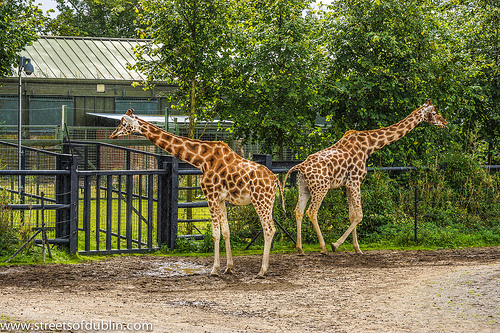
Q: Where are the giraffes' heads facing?
A: Opposite each other.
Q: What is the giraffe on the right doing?
A: Walking.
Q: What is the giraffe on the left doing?
A: Standing.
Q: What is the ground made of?
A: Dirt.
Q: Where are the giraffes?
A: Zoo.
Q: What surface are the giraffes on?
A: Dirt.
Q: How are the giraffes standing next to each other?
A: Back-to-back.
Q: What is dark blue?
A: The gate.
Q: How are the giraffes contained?
A: Fence.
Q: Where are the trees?
A: Behind the fence.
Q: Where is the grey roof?
A: On the building.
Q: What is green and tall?
A: The trees.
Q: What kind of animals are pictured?
A: Giraffes.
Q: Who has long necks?
A: Giraffes.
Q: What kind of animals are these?
A: Giraffes.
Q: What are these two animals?
A: Giraffes.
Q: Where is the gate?
A: To the left.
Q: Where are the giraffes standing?
A: On muddy ground.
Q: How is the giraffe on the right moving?
A: Walking.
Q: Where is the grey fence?
A: To the left of the animals.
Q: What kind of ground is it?
A: Dirt and mud.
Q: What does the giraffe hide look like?
A: Brown spots.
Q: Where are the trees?
A: Behind the giraffes.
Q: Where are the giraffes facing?
A: Opposite directions.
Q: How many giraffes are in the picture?
A: 2.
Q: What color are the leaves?
A: Green.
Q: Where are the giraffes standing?
A: On the dirt road.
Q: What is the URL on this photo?
A: www.streetsofdublin.com.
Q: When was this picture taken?
A: Daytime.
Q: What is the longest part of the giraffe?
A: The neck.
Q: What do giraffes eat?
A: The leaves of the tree.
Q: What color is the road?
A: Brown.